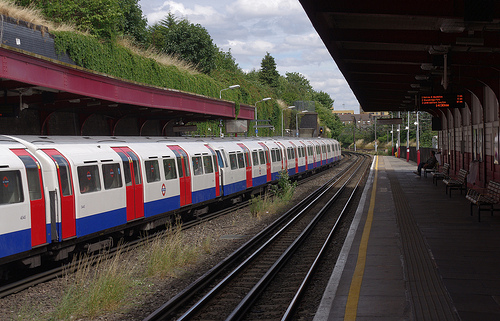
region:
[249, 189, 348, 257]
Tracks are brown color.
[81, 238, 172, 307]
Grass is green and brown color.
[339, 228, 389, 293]
Yellow and white lines in pavement.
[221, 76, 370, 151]
Lights are attached to the pole.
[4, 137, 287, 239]
Train is white, blue and red color.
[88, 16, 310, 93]
trees are behind the train.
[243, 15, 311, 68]
Clouds are white color.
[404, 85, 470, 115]
Letters are orange color.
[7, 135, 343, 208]
Windows on sides of the train.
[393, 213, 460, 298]
Pavement is grey color.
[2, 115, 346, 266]
Red, white and blue train.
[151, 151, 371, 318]
Train tracks along the train.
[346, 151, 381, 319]
Yellow warning line along the deck.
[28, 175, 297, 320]
Grass growing along the tracks.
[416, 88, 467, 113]
Informational sign on the platform.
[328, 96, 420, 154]
Building in the background.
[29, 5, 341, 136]
Trees in the background.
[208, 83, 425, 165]
Lights at the train station.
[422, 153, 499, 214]
Benches along the platform.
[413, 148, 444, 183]
Person sitting on the bench.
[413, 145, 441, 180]
the man is watching the train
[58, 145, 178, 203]
the train is red white and blue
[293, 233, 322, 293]
the train track is silver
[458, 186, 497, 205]
the bench is tan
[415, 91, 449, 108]
the words are orange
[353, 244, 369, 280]
the line is yellow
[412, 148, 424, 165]
the pole is red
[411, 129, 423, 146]
the pole is silver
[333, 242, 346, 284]
the line is white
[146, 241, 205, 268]
the grass is green in color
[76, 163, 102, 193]
a window on the side of a train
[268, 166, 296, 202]
tall wild grass growing beside the train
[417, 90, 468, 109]
orange text on a black sign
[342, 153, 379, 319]
a yellow painted line along a train track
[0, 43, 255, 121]
a red metal overhang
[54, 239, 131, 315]
wild green grass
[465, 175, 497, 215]
a bench against a train station wall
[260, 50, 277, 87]
a tall green tree on the hillside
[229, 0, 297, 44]
a light gray cloud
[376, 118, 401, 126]
a brown sign on a pole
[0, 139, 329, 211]
train is long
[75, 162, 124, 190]
passengers in the train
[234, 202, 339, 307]
four train tracks along the side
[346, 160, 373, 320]
yellow stripe line on the platform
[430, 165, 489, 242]
benches to sit on while waiting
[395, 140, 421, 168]
red poles in photo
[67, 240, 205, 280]
blades of grass near tracks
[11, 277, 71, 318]
stones on the ground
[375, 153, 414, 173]
sun reflection on platform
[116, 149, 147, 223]
door is red of train